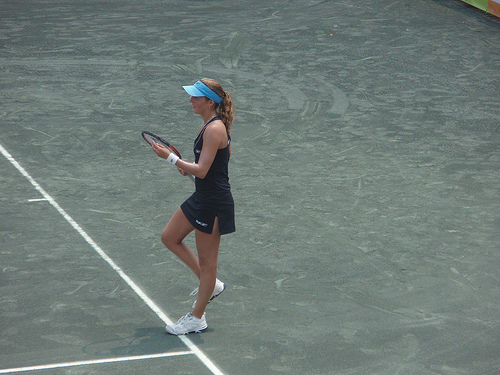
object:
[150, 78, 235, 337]
woman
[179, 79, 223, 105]
visor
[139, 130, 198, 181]
racket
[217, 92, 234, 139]
ponytail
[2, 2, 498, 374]
court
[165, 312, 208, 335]
shoes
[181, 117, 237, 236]
dress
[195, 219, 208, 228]
logo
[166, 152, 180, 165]
wristband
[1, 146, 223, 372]
lines